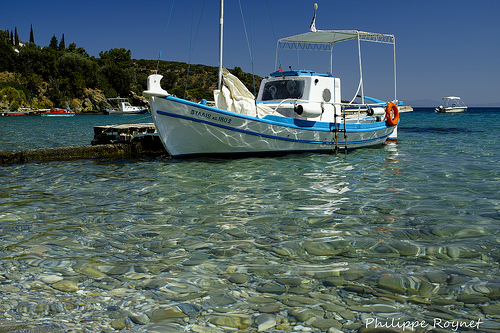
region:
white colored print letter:
[363, 316, 375, 328]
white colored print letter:
[372, 315, 383, 328]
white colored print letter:
[383, 315, 390, 327]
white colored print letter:
[395, 315, 402, 328]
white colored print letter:
[400, 319, 410, 331]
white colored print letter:
[410, 319, 422, 331]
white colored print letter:
[432, 316, 444, 330]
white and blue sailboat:
[145, 0, 399, 158]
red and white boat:
[39, 106, 75, 119]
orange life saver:
[383, 101, 400, 128]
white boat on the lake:
[433, 93, 468, 118]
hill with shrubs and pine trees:
[1, 20, 268, 105]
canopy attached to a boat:
[272, 28, 399, 108]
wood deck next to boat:
[92, 120, 167, 157]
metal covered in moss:
[0, 143, 122, 168]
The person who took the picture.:
[361, 315, 483, 332]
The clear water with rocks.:
[4, 105, 496, 322]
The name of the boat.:
[181, 105, 237, 132]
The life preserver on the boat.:
[375, 97, 413, 132]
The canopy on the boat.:
[269, 21, 409, 106]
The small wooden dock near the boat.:
[85, 118, 155, 156]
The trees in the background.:
[4, 22, 81, 51]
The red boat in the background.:
[38, 103, 79, 120]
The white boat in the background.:
[431, 85, 474, 130]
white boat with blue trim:
[139, 3, 401, 160]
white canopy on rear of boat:
[271, 1, 399, 103]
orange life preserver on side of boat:
[383, 93, 402, 129]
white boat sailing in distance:
[431, 87, 473, 122]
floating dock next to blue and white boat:
[87, 112, 164, 159]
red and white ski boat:
[43, 99, 76, 125]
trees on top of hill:
[43, 27, 72, 52]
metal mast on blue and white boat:
[214, 1, 226, 97]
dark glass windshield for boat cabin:
[259, 76, 307, 104]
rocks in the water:
[136, 282, 199, 317]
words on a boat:
[183, 100, 235, 143]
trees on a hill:
[89, 47, 132, 87]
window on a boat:
[320, 84, 335, 101]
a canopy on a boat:
[279, 21, 358, 73]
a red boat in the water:
[44, 98, 78, 126]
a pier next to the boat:
[98, 108, 146, 154]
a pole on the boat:
[206, 30, 235, 105]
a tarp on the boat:
[219, 69, 266, 123]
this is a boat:
[131, 4, 427, 211]